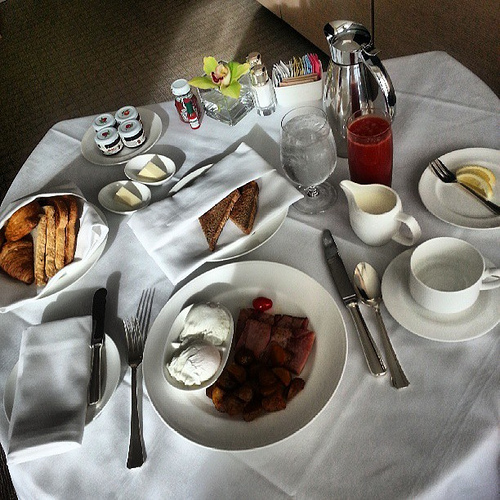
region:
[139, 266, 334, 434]
white plate on dinner table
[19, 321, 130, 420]
white plate on dinner table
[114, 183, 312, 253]
white plate on dinner table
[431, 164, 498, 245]
white plate on dinner table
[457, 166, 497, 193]
lemons cut up on plate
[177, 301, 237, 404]
white butter on plate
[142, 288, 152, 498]
silver fork on table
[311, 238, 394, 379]
silver knife on table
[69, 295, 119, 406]
silver knife on table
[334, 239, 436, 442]
silver spoon on table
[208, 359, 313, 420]
Potatoes on a plate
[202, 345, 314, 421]
Potatoes on a white plate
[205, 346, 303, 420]
Potatoes on a round plate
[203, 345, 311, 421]
Potatoes on a round white plate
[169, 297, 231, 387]
Eggs on a plate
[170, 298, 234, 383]
Eggs on a white plate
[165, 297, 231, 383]
Eggs on a round plate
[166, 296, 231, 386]
Eggs on a round white plate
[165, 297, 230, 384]
Poached eggs on a plate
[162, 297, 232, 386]
Poached eggs on a white plate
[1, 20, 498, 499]
table has a fancy breakfast meal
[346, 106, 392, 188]
tall glass of red pulpy juice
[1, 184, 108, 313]
slices of toast and croissants wrapped in white napkin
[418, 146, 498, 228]
white plate with fork and two lemon slices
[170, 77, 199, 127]
small bottles of ketchup and tabasco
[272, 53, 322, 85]
collection of sugar and artificial sweeteners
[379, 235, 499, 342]
empty white coffee cup and white saucer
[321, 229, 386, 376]
silver knife has been used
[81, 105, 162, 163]
collection of individually sized jellies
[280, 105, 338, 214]
ice water in a stemmed glass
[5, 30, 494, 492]
breakfast at a restaurant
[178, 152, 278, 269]
two pieces of toast in a napkin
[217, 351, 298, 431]
hash browns on a white plate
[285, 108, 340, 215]
glass filled with water and ice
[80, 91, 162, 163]
four jars of jelly on a plate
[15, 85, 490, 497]
table covered with a white table cloth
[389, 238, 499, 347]
white coffee cup and saucer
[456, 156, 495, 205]
two lemon slices on a plate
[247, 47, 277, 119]
salt and pepper shakers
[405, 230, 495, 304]
coffee cup is empty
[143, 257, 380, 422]
a plate on a table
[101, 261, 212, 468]
a fork near a plate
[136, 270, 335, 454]
food on a plate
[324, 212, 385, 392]
a knife on a table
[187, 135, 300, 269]
bread on a table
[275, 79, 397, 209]
a glass on a table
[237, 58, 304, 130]
salt on a table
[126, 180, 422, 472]
a white plate of food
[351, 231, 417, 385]
a spoon on a table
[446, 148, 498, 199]
lemons on a table